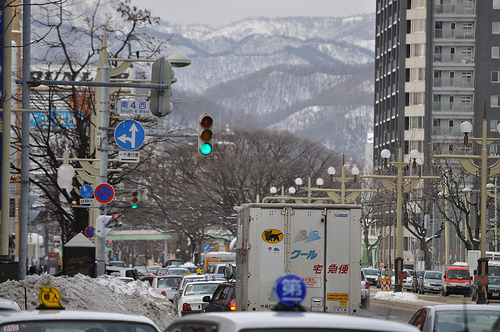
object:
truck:
[466, 249, 500, 279]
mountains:
[256, 97, 376, 164]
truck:
[233, 202, 362, 318]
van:
[442, 265, 473, 298]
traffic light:
[130, 190, 139, 211]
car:
[161, 309, 427, 332]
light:
[327, 165, 337, 176]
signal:
[196, 115, 213, 159]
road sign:
[117, 150, 142, 164]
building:
[368, 0, 499, 268]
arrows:
[117, 122, 140, 148]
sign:
[93, 182, 114, 205]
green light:
[199, 143, 213, 155]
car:
[407, 303, 500, 332]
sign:
[113, 119, 146, 151]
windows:
[466, 71, 473, 81]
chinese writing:
[312, 264, 323, 275]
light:
[350, 164, 360, 176]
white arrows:
[113, 119, 145, 151]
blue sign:
[113, 119, 146, 152]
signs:
[79, 184, 96, 198]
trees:
[399, 158, 448, 276]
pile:
[0, 272, 180, 330]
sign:
[32, 279, 67, 311]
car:
[0, 307, 163, 332]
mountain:
[188, 62, 378, 104]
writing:
[289, 249, 319, 260]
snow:
[368, 288, 421, 303]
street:
[360, 267, 500, 328]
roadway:
[364, 283, 500, 316]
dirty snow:
[0, 271, 178, 332]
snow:
[140, 12, 374, 154]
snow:
[0, 271, 173, 327]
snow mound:
[0, 272, 178, 331]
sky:
[25, 1, 374, 22]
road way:
[163, 264, 500, 332]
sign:
[116, 98, 154, 115]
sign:
[116, 150, 141, 163]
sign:
[79, 198, 94, 204]